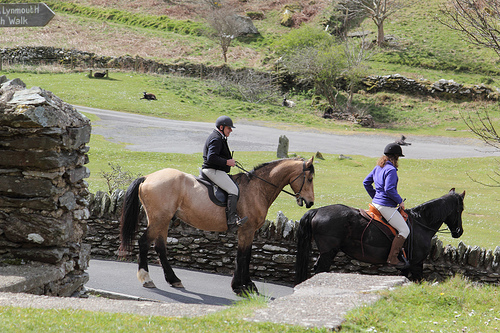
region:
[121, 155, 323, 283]
light brown horse standing on pavement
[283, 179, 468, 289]
dark brown horse trotting on pavement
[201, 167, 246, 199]
man in white pants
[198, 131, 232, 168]
man wearing navy sweater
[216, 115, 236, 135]
man in black helmet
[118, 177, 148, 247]
black fluffy hair of horse's tail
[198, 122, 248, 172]
man wearing a black jacket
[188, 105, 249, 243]
man on a brown horse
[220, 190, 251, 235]
man wearing black boots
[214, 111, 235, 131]
man wearing a black helmet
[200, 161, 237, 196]
man wearing brown pants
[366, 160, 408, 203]
woman wearing a purple shirt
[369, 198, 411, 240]
woman wearing white pants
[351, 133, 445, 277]
woman on a black horse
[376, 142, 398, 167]
woman with brown hair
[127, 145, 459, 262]
Jockeys on two horses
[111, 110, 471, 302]
people riding the horses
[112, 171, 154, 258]
a tail of the horse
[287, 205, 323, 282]
tail of the horse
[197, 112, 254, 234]
a person riding the horse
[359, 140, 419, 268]
a woman riding a horse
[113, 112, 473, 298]
two people riding horses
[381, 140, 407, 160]
a hat the woman is wearing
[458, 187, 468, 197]
an ear of the horse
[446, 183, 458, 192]
an ear of the horse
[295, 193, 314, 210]
a mouth of the horse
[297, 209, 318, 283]
A black horses long black tail.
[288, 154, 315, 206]
Brown horse head with open mouth.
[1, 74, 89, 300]
A tall dark grey stone wall edge.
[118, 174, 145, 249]
Dark brown shorter horse tail.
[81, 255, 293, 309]
Grey paved walkway horses are on.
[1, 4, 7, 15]
A grey letter L on a sign that is capitalized.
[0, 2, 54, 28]
A brown pointing sign with Walk written on it.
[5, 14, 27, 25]
The word Walk.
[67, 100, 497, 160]
A grey road past the horses.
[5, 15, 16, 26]
Grey W in Walk.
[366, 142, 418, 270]
this is a person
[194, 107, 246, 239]
this is a person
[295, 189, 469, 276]
this is a horse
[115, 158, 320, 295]
this is a horse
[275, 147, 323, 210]
the head of a horse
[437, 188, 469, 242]
the head of a horse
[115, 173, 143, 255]
the tail of a horse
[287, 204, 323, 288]
the tail of a horse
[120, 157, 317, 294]
this is a brown horse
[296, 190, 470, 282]
this is a black horse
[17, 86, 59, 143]
large rock on wall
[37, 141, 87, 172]
large rock on wall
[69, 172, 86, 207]
large rock on wall